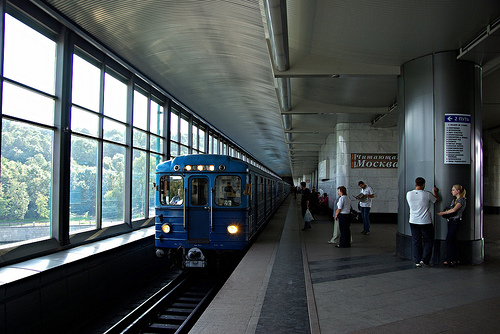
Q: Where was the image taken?
A: It was taken at the train station.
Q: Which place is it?
A: It is a train station.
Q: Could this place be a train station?
A: Yes, it is a train station.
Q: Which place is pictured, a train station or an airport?
A: It is a train station.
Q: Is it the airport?
A: No, it is the train station.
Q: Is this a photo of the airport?
A: No, the picture is showing the train station.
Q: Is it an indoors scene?
A: Yes, it is indoors.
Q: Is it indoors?
A: Yes, it is indoors.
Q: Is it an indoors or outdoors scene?
A: It is indoors.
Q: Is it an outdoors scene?
A: No, it is indoors.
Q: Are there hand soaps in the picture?
A: No, there are no hand soaps.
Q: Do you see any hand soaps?
A: No, there are no hand soaps.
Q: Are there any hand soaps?
A: No, there are no hand soaps.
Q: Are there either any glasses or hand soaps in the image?
A: No, there are no hand soaps or glasses.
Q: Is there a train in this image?
A: Yes, there is a train.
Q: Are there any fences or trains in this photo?
A: Yes, there is a train.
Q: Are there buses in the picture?
A: No, there are no buses.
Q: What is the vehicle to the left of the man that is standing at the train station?
A: The vehicle is a train.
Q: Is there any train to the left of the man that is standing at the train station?
A: Yes, there is a train to the left of the man.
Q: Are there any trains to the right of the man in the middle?
A: No, the train is to the left of the man.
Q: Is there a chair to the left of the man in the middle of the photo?
A: No, there is a train to the left of the man.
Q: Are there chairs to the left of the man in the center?
A: No, there is a train to the left of the man.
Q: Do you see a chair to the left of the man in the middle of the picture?
A: No, there is a train to the left of the man.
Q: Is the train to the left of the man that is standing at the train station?
A: Yes, the train is to the left of the man.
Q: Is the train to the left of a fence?
A: No, the train is to the left of the man.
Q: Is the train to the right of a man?
A: No, the train is to the left of a man.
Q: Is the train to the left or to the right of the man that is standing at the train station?
A: The train is to the left of the man.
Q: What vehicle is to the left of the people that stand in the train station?
A: The vehicle is a train.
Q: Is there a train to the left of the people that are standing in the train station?
A: Yes, there is a train to the left of the people.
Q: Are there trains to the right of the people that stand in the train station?
A: No, the train is to the left of the people.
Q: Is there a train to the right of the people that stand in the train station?
A: No, the train is to the left of the people.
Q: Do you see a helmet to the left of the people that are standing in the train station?
A: No, there is a train to the left of the people.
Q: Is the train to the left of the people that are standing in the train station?
A: Yes, the train is to the left of the people.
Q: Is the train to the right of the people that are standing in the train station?
A: No, the train is to the left of the people.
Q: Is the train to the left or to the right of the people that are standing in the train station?
A: The train is to the left of the people.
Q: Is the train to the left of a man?
A: Yes, the train is to the left of a man.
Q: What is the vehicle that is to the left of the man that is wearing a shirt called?
A: The vehicle is a train.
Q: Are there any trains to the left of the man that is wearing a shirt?
A: Yes, there is a train to the left of the man.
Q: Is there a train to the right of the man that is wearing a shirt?
A: No, the train is to the left of the man.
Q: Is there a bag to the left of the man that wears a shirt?
A: No, there is a train to the left of the man.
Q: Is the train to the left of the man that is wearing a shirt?
A: Yes, the train is to the left of the man.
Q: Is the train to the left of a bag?
A: No, the train is to the left of the man.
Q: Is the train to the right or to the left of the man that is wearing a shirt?
A: The train is to the left of the man.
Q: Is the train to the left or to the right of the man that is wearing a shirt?
A: The train is to the left of the man.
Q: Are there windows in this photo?
A: Yes, there is a window.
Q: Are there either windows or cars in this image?
A: Yes, there is a window.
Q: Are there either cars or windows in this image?
A: Yes, there is a window.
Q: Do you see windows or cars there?
A: Yes, there is a window.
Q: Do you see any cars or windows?
A: Yes, there is a window.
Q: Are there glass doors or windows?
A: Yes, there is a glass window.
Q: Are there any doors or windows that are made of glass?
A: Yes, the window is made of glass.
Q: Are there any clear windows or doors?
A: Yes, there is a clear window.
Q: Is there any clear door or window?
A: Yes, there is a clear window.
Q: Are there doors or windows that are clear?
A: Yes, the window is clear.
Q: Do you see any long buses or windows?
A: Yes, there is a long window.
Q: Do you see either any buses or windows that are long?
A: Yes, the window is long.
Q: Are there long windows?
A: Yes, there is a long window.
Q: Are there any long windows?
A: Yes, there is a long window.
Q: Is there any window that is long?
A: Yes, there is a window that is long.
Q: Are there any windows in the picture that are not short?
A: Yes, there is a long window.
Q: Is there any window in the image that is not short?
A: Yes, there is a long window.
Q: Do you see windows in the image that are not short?
A: Yes, there is a long window.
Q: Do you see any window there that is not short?
A: Yes, there is a long window.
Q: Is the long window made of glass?
A: Yes, the window is made of glass.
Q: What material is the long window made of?
A: The window is made of glass.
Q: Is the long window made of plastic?
A: No, the window is made of glass.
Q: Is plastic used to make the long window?
A: No, the window is made of glass.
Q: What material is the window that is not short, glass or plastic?
A: The window is made of glass.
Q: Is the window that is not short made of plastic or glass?
A: The window is made of glass.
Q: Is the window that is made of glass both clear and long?
A: Yes, the window is clear and long.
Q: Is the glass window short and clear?
A: No, the window is clear but long.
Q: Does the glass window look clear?
A: Yes, the window is clear.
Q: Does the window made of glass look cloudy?
A: No, the window is clear.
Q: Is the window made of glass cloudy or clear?
A: The window is clear.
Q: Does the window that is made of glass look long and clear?
A: Yes, the window is long and clear.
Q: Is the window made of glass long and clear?
A: Yes, the window is long and clear.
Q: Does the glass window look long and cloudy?
A: No, the window is long but clear.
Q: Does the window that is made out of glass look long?
A: Yes, the window is long.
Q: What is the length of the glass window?
A: The window is long.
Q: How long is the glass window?
A: The window is long.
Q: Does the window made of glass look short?
A: No, the window is long.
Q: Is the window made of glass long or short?
A: The window is long.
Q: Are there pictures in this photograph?
A: No, there are no pictures.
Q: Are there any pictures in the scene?
A: No, there are no pictures.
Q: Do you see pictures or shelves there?
A: No, there are no pictures or shelves.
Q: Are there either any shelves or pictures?
A: No, there are no pictures or shelves.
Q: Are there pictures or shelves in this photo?
A: No, there are no pictures or shelves.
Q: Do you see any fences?
A: No, there are no fences.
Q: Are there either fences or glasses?
A: No, there are no fences or glasses.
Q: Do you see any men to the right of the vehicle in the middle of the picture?
A: Yes, there is a man to the right of the train.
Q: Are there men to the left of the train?
A: No, the man is to the right of the train.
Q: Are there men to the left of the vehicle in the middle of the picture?
A: No, the man is to the right of the train.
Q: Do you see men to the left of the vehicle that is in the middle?
A: No, the man is to the right of the train.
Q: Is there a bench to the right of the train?
A: No, there is a man to the right of the train.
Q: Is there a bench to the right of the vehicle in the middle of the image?
A: No, there is a man to the right of the train.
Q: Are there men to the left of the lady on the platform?
A: Yes, there is a man to the left of the lady.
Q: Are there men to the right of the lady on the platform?
A: No, the man is to the left of the lady.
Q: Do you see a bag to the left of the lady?
A: No, there is a man to the left of the lady.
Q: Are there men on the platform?
A: Yes, there is a man on the platform.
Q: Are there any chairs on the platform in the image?
A: No, there is a man on the platform.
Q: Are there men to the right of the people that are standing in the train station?
A: Yes, there is a man to the right of the people.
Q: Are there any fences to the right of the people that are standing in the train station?
A: No, there is a man to the right of the people.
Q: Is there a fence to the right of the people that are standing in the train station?
A: No, there is a man to the right of the people.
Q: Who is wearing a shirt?
A: The man is wearing a shirt.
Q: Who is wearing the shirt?
A: The man is wearing a shirt.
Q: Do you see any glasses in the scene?
A: No, there are no glasses.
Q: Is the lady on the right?
A: Yes, the lady is on the right of the image.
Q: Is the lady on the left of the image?
A: No, the lady is on the right of the image.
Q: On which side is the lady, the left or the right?
A: The lady is on the right of the image.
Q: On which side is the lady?
A: The lady is on the right of the image.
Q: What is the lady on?
A: The lady is on the platform.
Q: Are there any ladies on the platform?
A: Yes, there is a lady on the platform.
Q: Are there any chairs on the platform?
A: No, there is a lady on the platform.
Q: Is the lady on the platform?
A: Yes, the lady is on the platform.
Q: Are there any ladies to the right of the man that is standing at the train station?
A: Yes, there is a lady to the right of the man.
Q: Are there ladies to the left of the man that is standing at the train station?
A: No, the lady is to the right of the man.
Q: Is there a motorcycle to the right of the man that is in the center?
A: No, there is a lady to the right of the man.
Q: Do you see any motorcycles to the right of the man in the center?
A: No, there is a lady to the right of the man.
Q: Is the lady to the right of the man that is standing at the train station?
A: Yes, the lady is to the right of the man.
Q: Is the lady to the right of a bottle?
A: No, the lady is to the right of the man.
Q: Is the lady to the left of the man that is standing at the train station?
A: No, the lady is to the right of the man.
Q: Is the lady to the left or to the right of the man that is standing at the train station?
A: The lady is to the right of the man.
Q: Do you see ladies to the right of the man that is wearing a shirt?
A: Yes, there is a lady to the right of the man.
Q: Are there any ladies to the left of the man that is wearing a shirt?
A: No, the lady is to the right of the man.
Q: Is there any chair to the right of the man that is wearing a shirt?
A: No, there is a lady to the right of the man.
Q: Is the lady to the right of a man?
A: Yes, the lady is to the right of a man.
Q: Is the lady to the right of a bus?
A: No, the lady is to the right of a man.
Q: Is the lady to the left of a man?
A: No, the lady is to the right of a man.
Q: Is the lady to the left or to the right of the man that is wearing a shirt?
A: The lady is to the right of the man.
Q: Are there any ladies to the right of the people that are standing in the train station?
A: Yes, there is a lady to the right of the people.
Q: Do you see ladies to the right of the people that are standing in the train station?
A: Yes, there is a lady to the right of the people.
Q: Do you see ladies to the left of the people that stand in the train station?
A: No, the lady is to the right of the people.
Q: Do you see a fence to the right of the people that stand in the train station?
A: No, there is a lady to the right of the people.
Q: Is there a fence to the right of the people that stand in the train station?
A: No, there is a lady to the right of the people.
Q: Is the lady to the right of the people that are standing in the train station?
A: Yes, the lady is to the right of the people.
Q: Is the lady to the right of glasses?
A: No, the lady is to the right of the people.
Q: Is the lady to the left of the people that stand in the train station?
A: No, the lady is to the right of the people.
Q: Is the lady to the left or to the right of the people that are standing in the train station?
A: The lady is to the right of the people.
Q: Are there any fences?
A: No, there are no fences.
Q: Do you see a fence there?
A: No, there are no fences.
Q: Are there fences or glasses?
A: No, there are no fences or glasses.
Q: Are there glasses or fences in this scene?
A: No, there are no fences or glasses.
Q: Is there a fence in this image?
A: No, there are no fences.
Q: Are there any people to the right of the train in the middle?
A: Yes, there are people to the right of the train.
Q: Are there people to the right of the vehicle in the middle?
A: Yes, there are people to the right of the train.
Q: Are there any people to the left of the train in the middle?
A: No, the people are to the right of the train.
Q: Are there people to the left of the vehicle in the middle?
A: No, the people are to the right of the train.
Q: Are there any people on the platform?
A: Yes, there are people on the platform.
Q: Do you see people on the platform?
A: Yes, there are people on the platform.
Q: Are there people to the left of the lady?
A: Yes, there are people to the left of the lady.